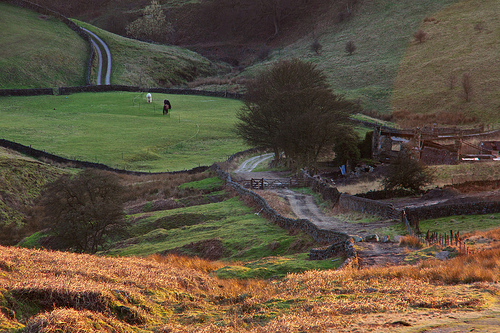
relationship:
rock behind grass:
[199, 239, 225, 261] [1, 244, 497, 330]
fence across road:
[236, 178, 314, 188] [237, 151, 407, 266]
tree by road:
[233, 58, 329, 169] [237, 151, 407, 266]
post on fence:
[224, 89, 231, 99] [0, 83, 243, 103]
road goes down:
[50, 10, 112, 87] [90, 70, 119, 87]